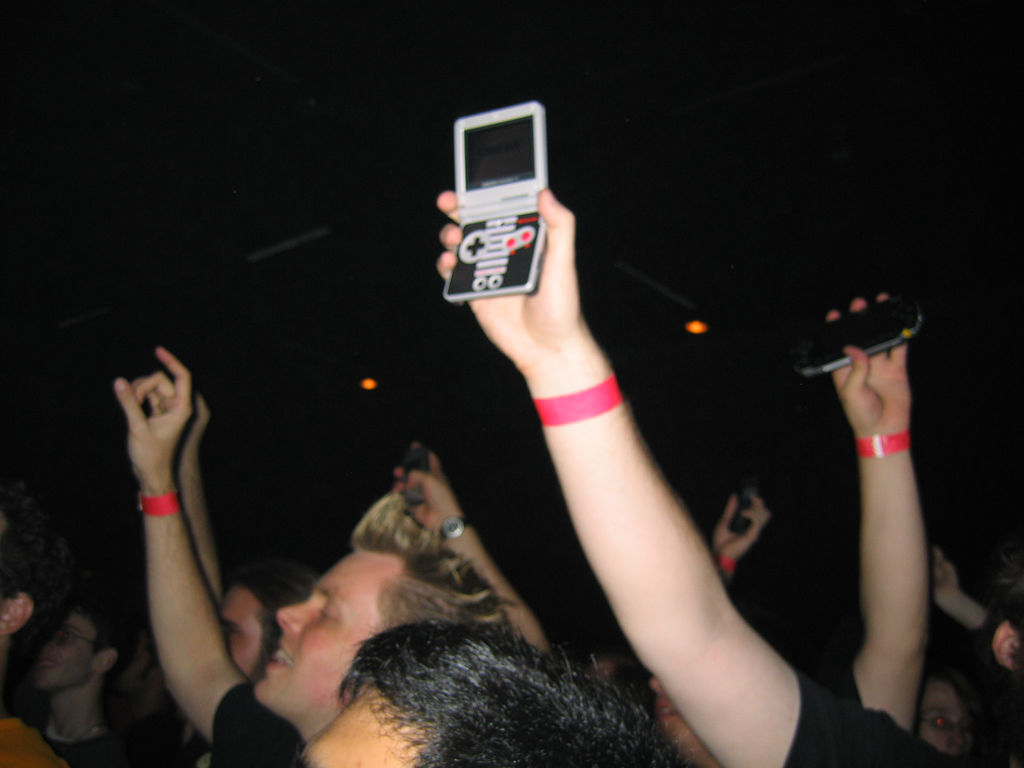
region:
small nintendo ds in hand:
[432, 128, 557, 287]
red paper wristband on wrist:
[541, 360, 627, 430]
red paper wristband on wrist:
[134, 490, 192, 511]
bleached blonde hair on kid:
[362, 485, 440, 558]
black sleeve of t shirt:
[770, 678, 920, 765]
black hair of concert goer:
[347, 617, 651, 755]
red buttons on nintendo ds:
[495, 229, 528, 255]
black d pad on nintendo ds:
[451, 224, 494, 256]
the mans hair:
[380, 622, 662, 766]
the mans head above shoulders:
[29, 587, 146, 730]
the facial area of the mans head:
[35, 609, 86, 704]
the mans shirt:
[781, 671, 917, 763]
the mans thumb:
[532, 187, 589, 299]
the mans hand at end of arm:
[87, 345, 220, 501]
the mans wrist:
[481, 312, 644, 436]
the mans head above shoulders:
[231, 455, 504, 740]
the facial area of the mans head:
[239, 546, 379, 709]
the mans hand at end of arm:
[411, 145, 605, 361]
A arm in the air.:
[157, 375, 246, 604]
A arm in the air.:
[422, 440, 536, 668]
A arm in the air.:
[424, 150, 835, 757]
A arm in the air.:
[923, 555, 994, 639]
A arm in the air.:
[699, 473, 766, 594]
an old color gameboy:
[438, 98, 550, 299]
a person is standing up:
[264, 617, 707, 766]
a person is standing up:
[114, 351, 501, 763]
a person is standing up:
[0, 589, 127, 766]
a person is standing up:
[903, 642, 970, 760]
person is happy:
[125, 339, 534, 766]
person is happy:
[0, 598, 117, 744]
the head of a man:
[215, 501, 473, 737]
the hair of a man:
[359, 479, 452, 575]